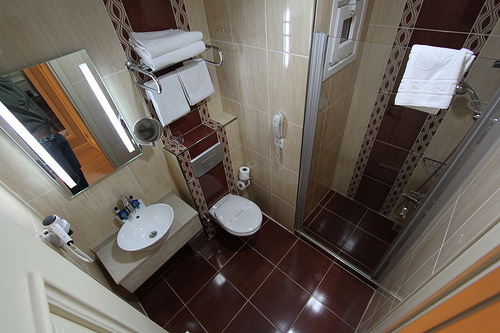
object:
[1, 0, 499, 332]
bathroom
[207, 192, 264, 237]
toilet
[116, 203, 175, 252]
sink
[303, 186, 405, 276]
ground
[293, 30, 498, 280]
door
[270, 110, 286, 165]
telephone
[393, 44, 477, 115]
towel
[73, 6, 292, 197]
wall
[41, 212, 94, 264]
dryer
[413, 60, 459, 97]
white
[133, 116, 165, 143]
mirror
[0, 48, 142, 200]
mirror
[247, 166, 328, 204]
wall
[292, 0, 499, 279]
shower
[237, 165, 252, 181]
rolls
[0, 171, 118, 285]
wall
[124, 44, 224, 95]
shelf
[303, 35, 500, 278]
glass